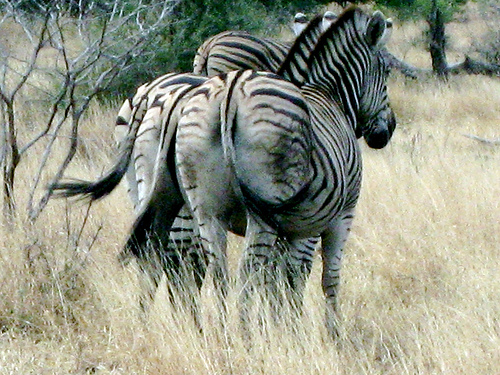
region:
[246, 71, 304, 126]
Black and white stripes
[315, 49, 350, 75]
Black and white stripes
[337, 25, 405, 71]
Black and white stripes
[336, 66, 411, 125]
Black and white stripes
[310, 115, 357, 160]
Black and white stripes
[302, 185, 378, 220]
Black and white stripes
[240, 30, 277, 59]
Black and white stripes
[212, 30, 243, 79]
Black and white stripes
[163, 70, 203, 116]
Black and white stripes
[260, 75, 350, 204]
Black and white stripes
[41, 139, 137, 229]
zebra's tail is black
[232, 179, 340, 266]
zebra's tail is black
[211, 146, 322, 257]
zebra's tail is black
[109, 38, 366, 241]
zebras' fur are stripes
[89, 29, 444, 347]
zebras' fur are stripes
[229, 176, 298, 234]
zebra's tail is black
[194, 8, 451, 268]
zebra's fur is stripes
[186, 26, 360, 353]
zebra's fur is stripes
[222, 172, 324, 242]
black hair on a zebra's tail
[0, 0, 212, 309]
a leafless tree growing in the tall grass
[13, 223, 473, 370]
the tall grass is brown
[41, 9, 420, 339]
a herd of zebras walking across a dry field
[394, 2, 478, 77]
a tree growing in the distance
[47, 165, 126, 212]
the black fur on a zebra's tail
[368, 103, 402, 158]
the zebra's black snout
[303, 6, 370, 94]
the zebra's black and white mane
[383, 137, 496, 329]
tall and dry grass in a field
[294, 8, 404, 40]
ears of two zebras